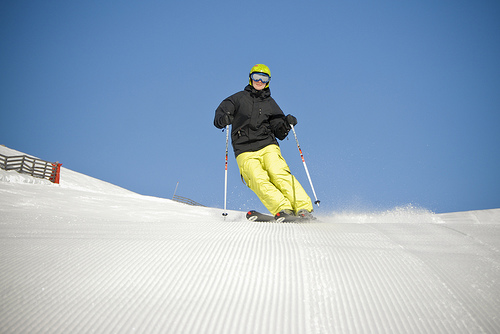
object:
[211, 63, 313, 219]
man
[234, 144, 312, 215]
pants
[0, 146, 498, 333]
snow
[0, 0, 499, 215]
sky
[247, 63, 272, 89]
helmet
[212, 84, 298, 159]
jacket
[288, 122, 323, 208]
pole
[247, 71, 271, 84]
goggles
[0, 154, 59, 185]
fence